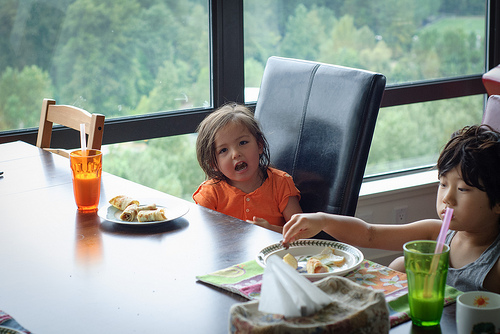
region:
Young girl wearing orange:
[178, 101, 303, 237]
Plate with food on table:
[100, 193, 188, 232]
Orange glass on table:
[63, 148, 101, 220]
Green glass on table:
[398, 241, 445, 328]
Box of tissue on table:
[215, 256, 393, 333]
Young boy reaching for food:
[257, 128, 498, 299]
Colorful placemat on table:
[189, 243, 464, 328]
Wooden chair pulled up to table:
[34, 95, 118, 197]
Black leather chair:
[245, 51, 380, 245]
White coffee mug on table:
[453, 288, 498, 332]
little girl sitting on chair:
[157, 89, 327, 236]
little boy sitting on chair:
[252, 106, 499, 305]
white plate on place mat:
[249, 215, 404, 305]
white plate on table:
[85, 184, 207, 244]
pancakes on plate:
[105, 185, 169, 233]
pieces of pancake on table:
[270, 228, 344, 275]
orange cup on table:
[43, 117, 108, 219]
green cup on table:
[391, 211, 451, 332]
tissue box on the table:
[200, 252, 406, 332]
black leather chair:
[214, 39, 394, 225]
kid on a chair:
[164, 85, 328, 220]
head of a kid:
[196, 98, 283, 192]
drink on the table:
[46, 126, 128, 226]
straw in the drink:
[73, 120, 99, 142]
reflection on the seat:
[297, 107, 348, 158]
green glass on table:
[372, 228, 467, 323]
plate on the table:
[261, 230, 358, 282]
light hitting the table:
[71, 248, 182, 298]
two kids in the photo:
[183, 69, 496, 279]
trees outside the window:
[68, 48, 181, 92]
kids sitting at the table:
[137, 63, 489, 305]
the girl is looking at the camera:
[161, 79, 295, 213]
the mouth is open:
[214, 157, 275, 189]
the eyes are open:
[205, 125, 258, 160]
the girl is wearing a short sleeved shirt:
[168, 162, 311, 222]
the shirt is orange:
[173, 148, 305, 230]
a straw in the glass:
[71, 112, 91, 214]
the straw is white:
[74, 118, 89, 201]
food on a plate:
[88, 187, 191, 247]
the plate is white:
[87, 175, 202, 258]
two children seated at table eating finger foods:
[82, 96, 497, 291]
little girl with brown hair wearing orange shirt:
[189, 102, 307, 216]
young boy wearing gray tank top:
[410, 116, 499, 287]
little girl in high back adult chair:
[192, 51, 404, 221]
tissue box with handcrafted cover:
[196, 263, 398, 330]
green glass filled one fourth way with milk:
[396, 208, 468, 328]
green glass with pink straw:
[379, 207, 468, 322]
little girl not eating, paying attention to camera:
[185, 99, 293, 213]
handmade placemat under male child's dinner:
[198, 245, 452, 322]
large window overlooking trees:
[3, 5, 497, 175]